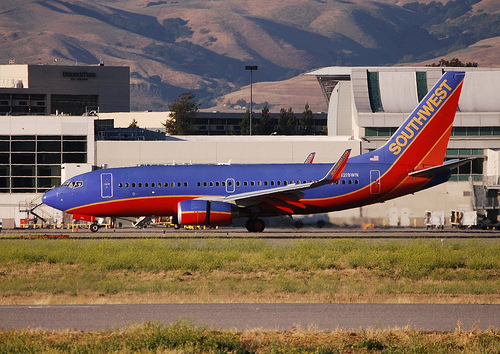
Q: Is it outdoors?
A: Yes, it is outdoors.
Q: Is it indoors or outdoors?
A: It is outdoors.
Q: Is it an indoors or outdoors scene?
A: It is outdoors.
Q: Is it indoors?
A: No, it is outdoors.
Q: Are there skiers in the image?
A: No, there are no skiers.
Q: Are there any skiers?
A: No, there are no skiers.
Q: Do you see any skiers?
A: No, there are no skiers.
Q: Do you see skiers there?
A: No, there are no skiers.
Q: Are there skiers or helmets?
A: No, there are no skiers or helmets.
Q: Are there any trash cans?
A: No, there are no trash cans.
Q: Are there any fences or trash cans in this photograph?
A: No, there are no trash cans or fences.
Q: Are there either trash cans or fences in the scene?
A: No, there are no trash cans or fences.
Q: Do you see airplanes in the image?
A: Yes, there is an airplane.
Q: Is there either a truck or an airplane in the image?
A: Yes, there is an airplane.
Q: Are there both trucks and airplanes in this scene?
A: No, there is an airplane but no trucks.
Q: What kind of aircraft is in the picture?
A: The aircraft is an airplane.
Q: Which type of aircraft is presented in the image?
A: The aircraft is an airplane.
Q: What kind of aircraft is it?
A: The aircraft is an airplane.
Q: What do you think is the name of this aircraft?
A: This is an airplane.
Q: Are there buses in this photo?
A: No, there are no buses.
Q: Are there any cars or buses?
A: No, there are no buses or cars.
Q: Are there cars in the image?
A: No, there are no cars.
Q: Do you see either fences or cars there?
A: No, there are no cars or fences.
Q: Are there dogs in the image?
A: No, there are no dogs.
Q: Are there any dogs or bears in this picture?
A: No, there are no dogs or bears.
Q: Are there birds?
A: No, there are no birds.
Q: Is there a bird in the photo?
A: No, there are no birds.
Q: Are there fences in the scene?
A: No, there are no fences.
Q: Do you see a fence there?
A: No, there are no fences.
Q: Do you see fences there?
A: No, there are no fences.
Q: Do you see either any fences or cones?
A: No, there are no fences or cones.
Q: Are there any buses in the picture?
A: No, there are no buses.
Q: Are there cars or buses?
A: No, there are no buses or cars.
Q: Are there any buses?
A: No, there are no buses.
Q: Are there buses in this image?
A: No, there are no buses.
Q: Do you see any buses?
A: No, there are no buses.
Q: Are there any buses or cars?
A: No, there are no buses or cars.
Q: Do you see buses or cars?
A: No, there are no buses or cars.